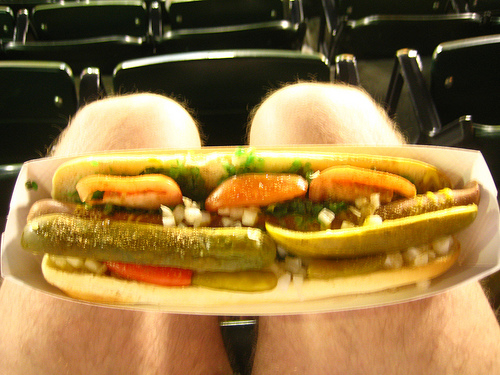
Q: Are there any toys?
A: No, there are no toys.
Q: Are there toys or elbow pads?
A: No, there are no toys or elbow pads.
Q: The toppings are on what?
A: The toppings are on the hot dog.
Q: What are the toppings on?
A: The toppings are on the hot dog.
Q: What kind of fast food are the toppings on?
A: The toppings are on the hot dog.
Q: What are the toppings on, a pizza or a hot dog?
A: The toppings are on a hot dog.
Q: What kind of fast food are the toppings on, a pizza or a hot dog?
A: The toppings are on a hot dog.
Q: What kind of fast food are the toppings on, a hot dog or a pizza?
A: The toppings are on a hot dog.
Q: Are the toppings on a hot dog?
A: Yes, the toppings are on a hot dog.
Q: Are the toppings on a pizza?
A: No, the toppings are on a hot dog.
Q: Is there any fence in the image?
A: No, there are no fences.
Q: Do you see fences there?
A: No, there are no fences.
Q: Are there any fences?
A: No, there are no fences.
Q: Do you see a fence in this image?
A: No, there are no fences.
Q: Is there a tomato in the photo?
A: Yes, there is a tomato.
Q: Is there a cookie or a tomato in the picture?
A: Yes, there is a tomato.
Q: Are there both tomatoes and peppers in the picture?
A: Yes, there are both a tomato and a pepper.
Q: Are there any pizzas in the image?
A: No, there are no pizzas.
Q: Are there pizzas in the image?
A: No, there are no pizzas.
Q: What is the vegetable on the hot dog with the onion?
A: The vegetable is a tomato.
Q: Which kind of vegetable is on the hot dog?
A: The vegetable is a tomato.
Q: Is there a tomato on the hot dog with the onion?
A: Yes, there is a tomato on the hot dog.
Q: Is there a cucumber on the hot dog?
A: No, there is a tomato on the hot dog.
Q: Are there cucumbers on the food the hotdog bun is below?
A: No, there is a tomato on the hot dog.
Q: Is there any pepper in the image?
A: Yes, there is a pepper.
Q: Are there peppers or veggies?
A: Yes, there is a pepper.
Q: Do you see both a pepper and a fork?
A: No, there is a pepper but no forks.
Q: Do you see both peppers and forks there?
A: No, there is a pepper but no forks.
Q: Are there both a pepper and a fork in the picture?
A: No, there is a pepper but no forks.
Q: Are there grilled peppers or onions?
A: Yes, there is a grilled pepper.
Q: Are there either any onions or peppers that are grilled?
A: Yes, the pepper is grilled.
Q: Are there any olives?
A: No, there are no olives.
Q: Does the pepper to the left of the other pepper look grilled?
A: Yes, the pepper is grilled.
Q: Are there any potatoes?
A: No, there are no potatoes.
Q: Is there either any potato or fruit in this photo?
A: No, there are no potatoes or fruits.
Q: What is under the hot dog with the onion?
A: The hotdog bun is under the hot dog.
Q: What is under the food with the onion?
A: The hotdog bun is under the hot dog.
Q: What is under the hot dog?
A: The hotdog bun is under the hot dog.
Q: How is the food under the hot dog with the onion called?
A: The food is a hotdog bun.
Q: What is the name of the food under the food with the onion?
A: The food is a hotdog bun.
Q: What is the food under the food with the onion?
A: The food is a hotdog bun.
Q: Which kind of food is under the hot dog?
A: The food is a hotdog bun.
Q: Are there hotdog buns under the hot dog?
A: Yes, there is a hotdog bun under the hot dog.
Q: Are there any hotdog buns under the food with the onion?
A: Yes, there is a hotdog bun under the hot dog.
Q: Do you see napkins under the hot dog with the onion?
A: No, there is a hotdog bun under the hot dog.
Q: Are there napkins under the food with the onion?
A: No, there is a hotdog bun under the hot dog.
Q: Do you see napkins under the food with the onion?
A: No, there is a hotdog bun under the hot dog.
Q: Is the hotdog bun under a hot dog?
A: Yes, the hotdog bun is under a hot dog.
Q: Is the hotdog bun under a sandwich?
A: No, the hotdog bun is under a hot dog.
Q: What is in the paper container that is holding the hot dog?
A: The hotdog bun is in the box.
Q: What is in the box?
A: The hotdog bun is in the box.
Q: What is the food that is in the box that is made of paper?
A: The food is a hotdog bun.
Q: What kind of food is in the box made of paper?
A: The food is a hotdog bun.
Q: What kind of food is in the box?
A: The food is a hotdog bun.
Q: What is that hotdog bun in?
A: The hotdog bun is in the box.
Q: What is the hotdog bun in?
A: The hotdog bun is in the box.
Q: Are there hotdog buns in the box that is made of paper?
A: Yes, there is a hotdog bun in the box.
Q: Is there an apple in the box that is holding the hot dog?
A: No, there is a hotdog bun in the box.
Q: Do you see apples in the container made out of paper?
A: No, there is a hotdog bun in the box.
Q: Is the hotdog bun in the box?
A: Yes, the hotdog bun is in the box.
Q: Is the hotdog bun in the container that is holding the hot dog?
A: Yes, the hotdog bun is in the box.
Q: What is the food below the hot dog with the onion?
A: The food is a hotdog bun.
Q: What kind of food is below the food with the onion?
A: The food is a hotdog bun.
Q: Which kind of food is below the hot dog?
A: The food is a hotdog bun.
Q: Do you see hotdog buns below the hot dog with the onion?
A: Yes, there is a hotdog bun below the hot dog.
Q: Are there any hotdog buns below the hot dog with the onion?
A: Yes, there is a hotdog bun below the hot dog.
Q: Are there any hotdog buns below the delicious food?
A: Yes, there is a hotdog bun below the hot dog.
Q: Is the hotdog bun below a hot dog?
A: Yes, the hotdog bun is below a hot dog.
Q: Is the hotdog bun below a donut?
A: No, the hotdog bun is below a hot dog.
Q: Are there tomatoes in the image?
A: Yes, there is a tomato.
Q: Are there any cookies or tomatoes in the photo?
A: Yes, there is a tomato.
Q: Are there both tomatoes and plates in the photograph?
A: No, there is a tomato but no plates.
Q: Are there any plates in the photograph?
A: No, there are no plates.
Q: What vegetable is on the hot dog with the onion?
A: The vegetable is a tomato.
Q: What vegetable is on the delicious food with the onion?
A: The vegetable is a tomato.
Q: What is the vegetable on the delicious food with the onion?
A: The vegetable is a tomato.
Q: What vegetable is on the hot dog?
A: The vegetable is a tomato.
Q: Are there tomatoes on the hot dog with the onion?
A: Yes, there is a tomato on the hot dog.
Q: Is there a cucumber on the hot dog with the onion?
A: No, there is a tomato on the hot dog.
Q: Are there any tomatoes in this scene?
A: Yes, there is a tomato.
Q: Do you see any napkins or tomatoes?
A: Yes, there is a tomato.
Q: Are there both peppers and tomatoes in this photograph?
A: Yes, there are both a tomato and a pepper.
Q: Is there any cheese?
A: No, there is no cheese.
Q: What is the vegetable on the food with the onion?
A: The vegetable is a tomato.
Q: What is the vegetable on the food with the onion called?
A: The vegetable is a tomato.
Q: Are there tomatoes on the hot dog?
A: Yes, there is a tomato on the hot dog.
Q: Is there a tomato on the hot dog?
A: Yes, there is a tomato on the hot dog.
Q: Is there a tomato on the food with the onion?
A: Yes, there is a tomato on the hot dog.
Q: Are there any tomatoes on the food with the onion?
A: Yes, there is a tomato on the hot dog.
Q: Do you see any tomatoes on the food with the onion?
A: Yes, there is a tomato on the hot dog.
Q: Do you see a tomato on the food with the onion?
A: Yes, there is a tomato on the hot dog.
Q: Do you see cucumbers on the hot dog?
A: No, there is a tomato on the hot dog.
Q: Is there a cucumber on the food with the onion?
A: No, there is a tomato on the hot dog.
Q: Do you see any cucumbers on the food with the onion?
A: No, there is a tomato on the hot dog.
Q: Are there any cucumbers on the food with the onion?
A: No, there is a tomato on the hot dog.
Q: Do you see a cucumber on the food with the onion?
A: No, there is a tomato on the hot dog.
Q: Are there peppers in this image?
A: Yes, there is a pepper.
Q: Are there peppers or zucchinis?
A: Yes, there is a pepper.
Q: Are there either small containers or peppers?
A: Yes, there is a small pepper.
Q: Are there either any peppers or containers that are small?
A: Yes, the pepper is small.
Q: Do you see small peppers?
A: Yes, there is a small pepper.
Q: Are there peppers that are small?
A: Yes, there is a pepper that is small.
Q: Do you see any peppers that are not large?
A: Yes, there is a small pepper.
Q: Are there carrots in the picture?
A: No, there are no carrots.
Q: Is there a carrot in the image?
A: No, there are no carrots.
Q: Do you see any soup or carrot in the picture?
A: No, there are no carrots or soup.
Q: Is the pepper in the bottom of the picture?
A: Yes, the pepper is in the bottom of the image.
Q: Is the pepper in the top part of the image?
A: No, the pepper is in the bottom of the image.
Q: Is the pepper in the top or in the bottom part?
A: The pepper is in the bottom of the image.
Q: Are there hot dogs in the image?
A: Yes, there is a hot dog.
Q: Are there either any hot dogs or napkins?
A: Yes, there is a hot dog.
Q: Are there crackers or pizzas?
A: No, there are no pizzas or crackers.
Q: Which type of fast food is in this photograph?
A: The fast food is a hot dog.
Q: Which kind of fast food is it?
A: The food is a hot dog.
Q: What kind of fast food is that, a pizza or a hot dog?
A: This is a hot dog.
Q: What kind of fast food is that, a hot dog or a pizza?
A: This is a hot dog.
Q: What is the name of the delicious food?
A: The food is a hot dog.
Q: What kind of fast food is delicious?
A: The fast food is a hot dog.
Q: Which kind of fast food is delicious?
A: The fast food is a hot dog.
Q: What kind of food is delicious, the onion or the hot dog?
A: The hot dog is delicious.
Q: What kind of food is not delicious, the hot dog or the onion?
A: The onion is not delicious.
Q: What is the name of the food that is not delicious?
A: The food is an onion.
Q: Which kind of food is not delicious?
A: The food is an onion.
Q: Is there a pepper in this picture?
A: Yes, there is a pepper.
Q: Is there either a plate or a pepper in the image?
A: Yes, there is a pepper.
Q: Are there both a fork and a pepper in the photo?
A: No, there is a pepper but no forks.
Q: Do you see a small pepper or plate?
A: Yes, there is a small pepper.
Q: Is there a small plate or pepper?
A: Yes, there is a small pepper.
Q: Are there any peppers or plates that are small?
A: Yes, the pepper is small.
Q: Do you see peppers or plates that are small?
A: Yes, the pepper is small.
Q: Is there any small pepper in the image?
A: Yes, there is a small pepper.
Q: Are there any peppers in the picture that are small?
A: Yes, there is a pepper that is small.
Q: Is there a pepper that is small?
A: Yes, there is a pepper that is small.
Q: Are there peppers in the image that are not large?
A: Yes, there is a small pepper.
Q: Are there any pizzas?
A: No, there are no pizzas.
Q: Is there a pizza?
A: No, there are no pizzas.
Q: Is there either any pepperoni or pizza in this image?
A: No, there are no pizzas or pepperoni.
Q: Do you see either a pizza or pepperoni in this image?
A: No, there are no pizzas or pepperoni.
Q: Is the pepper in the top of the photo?
A: No, the pepper is in the bottom of the image.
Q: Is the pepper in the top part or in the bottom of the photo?
A: The pepper is in the bottom of the image.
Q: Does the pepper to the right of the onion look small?
A: Yes, the pepper is small.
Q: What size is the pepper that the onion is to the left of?
A: The pepper is small.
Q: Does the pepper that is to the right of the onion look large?
A: No, the pepper is small.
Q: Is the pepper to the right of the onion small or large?
A: The pepper is small.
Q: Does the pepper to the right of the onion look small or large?
A: The pepper is small.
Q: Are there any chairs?
A: Yes, there is a chair.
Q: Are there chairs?
A: Yes, there is a chair.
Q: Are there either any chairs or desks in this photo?
A: Yes, there is a chair.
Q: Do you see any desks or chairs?
A: Yes, there is a chair.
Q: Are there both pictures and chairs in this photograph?
A: No, there is a chair but no pictures.